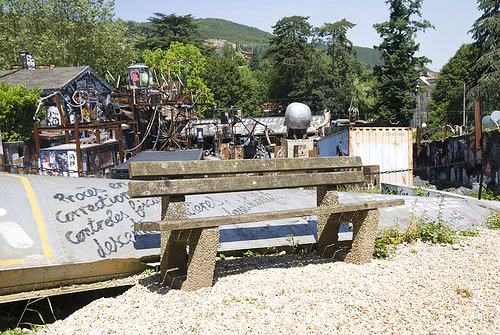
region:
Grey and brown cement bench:
[114, 149, 391, 303]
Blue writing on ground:
[46, 153, 303, 264]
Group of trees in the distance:
[8, 3, 499, 152]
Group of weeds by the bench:
[354, 199, 494, 281]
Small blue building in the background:
[0, 40, 225, 195]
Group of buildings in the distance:
[197, 36, 277, 80]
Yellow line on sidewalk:
[10, 171, 75, 271]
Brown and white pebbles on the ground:
[21, 221, 499, 333]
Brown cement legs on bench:
[157, 209, 387, 291]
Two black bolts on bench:
[149, 163, 179, 201]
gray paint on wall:
[9, 255, 46, 270]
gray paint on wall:
[12, 215, 39, 227]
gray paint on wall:
[29, 195, 51, 201]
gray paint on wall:
[453, 204, 469, 212]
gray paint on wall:
[345, 232, 358, 233]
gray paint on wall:
[390, 212, 401, 225]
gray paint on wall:
[272, 195, 311, 203]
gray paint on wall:
[401, 187, 480, 212]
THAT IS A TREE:
[260, 15, 318, 125]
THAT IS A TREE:
[329, 10, 352, 77]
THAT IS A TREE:
[363, 0, 429, 124]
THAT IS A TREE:
[444, 26, 495, 108]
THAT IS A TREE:
[204, 49, 247, 102]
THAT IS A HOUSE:
[14, 56, 107, 94]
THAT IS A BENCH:
[115, 141, 377, 243]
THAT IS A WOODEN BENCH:
[139, 159, 390, 237]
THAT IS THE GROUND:
[363, 255, 468, 302]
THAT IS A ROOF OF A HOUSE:
[198, 107, 323, 135]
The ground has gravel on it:
[248, 280, 453, 330]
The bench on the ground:
[126, 154, 413, 292]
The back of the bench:
[114, 147, 369, 199]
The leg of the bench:
[156, 228, 223, 290]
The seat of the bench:
[128, 190, 413, 237]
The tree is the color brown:
[381, 16, 419, 114]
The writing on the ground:
[38, 176, 134, 258]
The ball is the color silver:
[279, 98, 314, 134]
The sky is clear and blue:
[223, 4, 462, 39]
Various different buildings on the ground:
[38, 55, 313, 159]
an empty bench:
[126, 143, 411, 297]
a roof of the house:
[0, 63, 90, 90]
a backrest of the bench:
[121, 153, 369, 203]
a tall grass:
[15, 280, 60, 333]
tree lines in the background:
[1, 2, 499, 66]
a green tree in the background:
[258, 13, 327, 95]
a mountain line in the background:
[122, 12, 424, 62]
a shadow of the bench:
[133, 241, 383, 296]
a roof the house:
[177, 110, 328, 139]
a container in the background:
[316, 123, 416, 185]